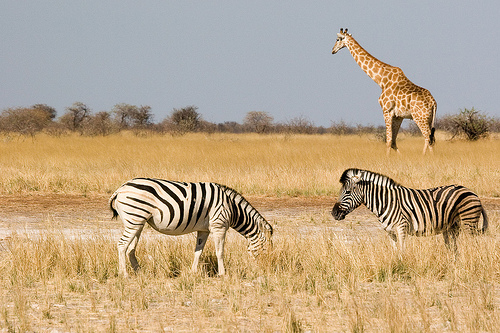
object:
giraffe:
[331, 27, 437, 158]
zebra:
[331, 167, 489, 251]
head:
[247, 234, 275, 260]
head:
[331, 27, 349, 54]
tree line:
[58, 101, 126, 138]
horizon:
[0, 124, 500, 139]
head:
[330, 168, 367, 221]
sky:
[0, 0, 499, 128]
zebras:
[109, 177, 274, 278]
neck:
[349, 41, 392, 75]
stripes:
[402, 189, 436, 233]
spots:
[391, 87, 408, 104]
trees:
[0, 103, 59, 139]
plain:
[0, 140, 499, 333]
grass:
[0, 139, 499, 202]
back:
[401, 185, 447, 198]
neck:
[368, 174, 394, 218]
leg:
[380, 101, 392, 153]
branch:
[82, 113, 109, 133]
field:
[0, 0, 499, 331]